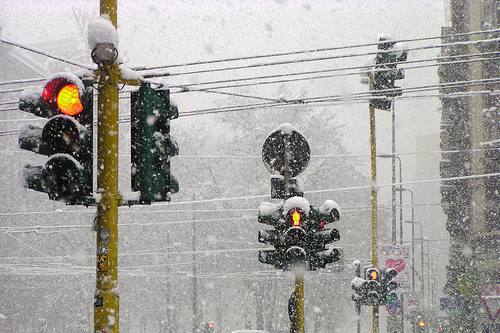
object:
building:
[437, 0, 498, 333]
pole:
[92, 1, 115, 331]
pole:
[368, 105, 378, 329]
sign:
[378, 245, 413, 294]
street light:
[369, 34, 408, 111]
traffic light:
[18, 72, 179, 206]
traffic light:
[387, 268, 398, 304]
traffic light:
[415, 312, 427, 332]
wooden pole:
[191, 191, 196, 331]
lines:
[0, 38, 295, 108]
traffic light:
[257, 197, 340, 269]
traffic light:
[367, 268, 381, 306]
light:
[292, 209, 301, 226]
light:
[41, 71, 89, 116]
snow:
[284, 196, 310, 214]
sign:
[262, 129, 311, 177]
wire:
[124, 28, 500, 72]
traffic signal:
[131, 81, 179, 202]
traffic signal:
[18, 72, 93, 206]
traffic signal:
[257, 197, 342, 271]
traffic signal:
[351, 266, 397, 305]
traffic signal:
[365, 268, 377, 305]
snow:
[0, 0, 500, 333]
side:
[0, 0, 102, 333]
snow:
[85, 14, 118, 44]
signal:
[42, 75, 88, 114]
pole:
[292, 268, 302, 331]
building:
[0, 40, 150, 333]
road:
[344, 310, 409, 333]